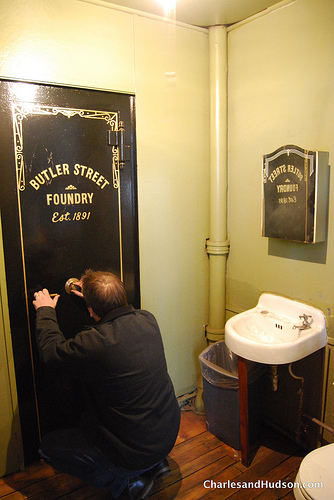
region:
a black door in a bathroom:
[0, 68, 145, 485]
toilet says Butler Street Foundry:
[15, 144, 116, 233]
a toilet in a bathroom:
[288, 433, 330, 495]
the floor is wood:
[183, 433, 284, 496]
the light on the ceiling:
[149, 0, 182, 20]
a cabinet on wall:
[253, 142, 328, 249]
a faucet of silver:
[286, 304, 313, 334]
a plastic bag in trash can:
[188, 338, 250, 452]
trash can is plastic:
[187, 339, 283, 454]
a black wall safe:
[0, 76, 160, 466]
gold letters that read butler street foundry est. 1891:
[31, 150, 114, 230]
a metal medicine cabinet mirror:
[257, 137, 328, 250]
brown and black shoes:
[110, 454, 172, 495]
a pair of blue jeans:
[38, 409, 171, 489]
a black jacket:
[35, 291, 191, 474]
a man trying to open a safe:
[30, 261, 189, 495]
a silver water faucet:
[294, 312, 314, 332]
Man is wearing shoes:
[112, 451, 176, 498]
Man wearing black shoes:
[117, 454, 174, 497]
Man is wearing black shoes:
[116, 454, 171, 498]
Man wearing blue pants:
[37, 421, 172, 496]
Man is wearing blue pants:
[33, 423, 171, 497]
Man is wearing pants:
[36, 411, 167, 498]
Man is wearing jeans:
[38, 421, 166, 498]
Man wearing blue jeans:
[38, 418, 173, 497]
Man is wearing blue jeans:
[38, 424, 169, 496]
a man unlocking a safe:
[11, 272, 314, 468]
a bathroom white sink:
[232, 286, 332, 436]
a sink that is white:
[215, 282, 323, 410]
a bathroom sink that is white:
[191, 283, 319, 391]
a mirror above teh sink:
[262, 141, 331, 227]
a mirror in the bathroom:
[257, 136, 328, 284]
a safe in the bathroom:
[39, 95, 258, 436]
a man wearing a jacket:
[79, 283, 256, 497]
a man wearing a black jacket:
[31, 265, 253, 487]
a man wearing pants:
[44, 292, 220, 493]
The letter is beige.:
[25, 175, 38, 194]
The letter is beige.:
[33, 169, 44, 185]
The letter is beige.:
[39, 166, 50, 182]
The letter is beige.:
[46, 163, 57, 181]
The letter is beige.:
[54, 160, 64, 179]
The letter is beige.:
[60, 159, 70, 179]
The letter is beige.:
[41, 190, 54, 206]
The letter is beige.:
[65, 191, 74, 208]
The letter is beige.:
[85, 188, 95, 206]